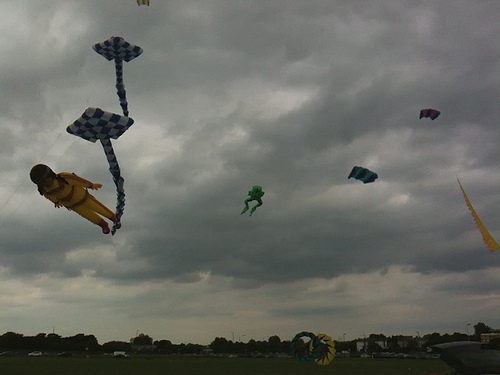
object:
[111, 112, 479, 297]
clouds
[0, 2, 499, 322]
sky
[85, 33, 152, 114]
kite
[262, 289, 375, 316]
cloud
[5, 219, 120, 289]
cloud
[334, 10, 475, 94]
cloud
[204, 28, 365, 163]
cloud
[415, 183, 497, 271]
cloud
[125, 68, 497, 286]
cloud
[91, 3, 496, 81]
cloud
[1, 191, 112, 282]
cloud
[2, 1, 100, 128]
cloud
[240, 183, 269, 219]
green kite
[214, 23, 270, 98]
clouds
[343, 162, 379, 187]
kite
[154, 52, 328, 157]
clouds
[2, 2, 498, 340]
cloudy sky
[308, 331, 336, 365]
circle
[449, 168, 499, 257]
kite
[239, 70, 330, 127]
cloud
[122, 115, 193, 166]
cloud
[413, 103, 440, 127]
kite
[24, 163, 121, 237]
kite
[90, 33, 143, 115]
kite